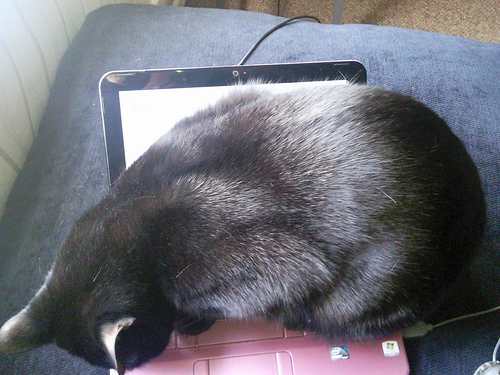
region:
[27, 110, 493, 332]
The cat is standing.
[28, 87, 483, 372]
The cat is sniffing.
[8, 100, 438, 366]
The cat is black.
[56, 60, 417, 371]
The computer is under the cat.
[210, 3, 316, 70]
The cord is black.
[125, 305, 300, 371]
The board is pink.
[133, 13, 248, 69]
The blanket is blue.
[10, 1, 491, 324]
The sun is shining through.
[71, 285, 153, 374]
His ear is shining.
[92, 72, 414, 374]
Small pretty pink lap top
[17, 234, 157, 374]
Curious cat looking at lap top.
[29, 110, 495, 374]
Black cat.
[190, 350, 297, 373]
Pink touch screen mouse.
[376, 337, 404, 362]
Logo of computer manufacturer.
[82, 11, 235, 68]
Comfy blue couch cushion.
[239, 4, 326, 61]
Power supply of computer.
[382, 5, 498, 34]
Short brown shag carpet.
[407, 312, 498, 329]
White computer cord.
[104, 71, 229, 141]
Portion of lap top screen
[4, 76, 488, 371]
cat laying on laptop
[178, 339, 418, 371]
pink windows laptop computer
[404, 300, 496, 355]
green cord connecting to peripheral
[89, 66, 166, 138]
laptop open display monitor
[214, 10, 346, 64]
power cord for laptop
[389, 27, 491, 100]
large blue pillow on couch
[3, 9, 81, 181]
white and green pillow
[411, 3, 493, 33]
different colored brown carpet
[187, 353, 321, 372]
touch pad and two buttons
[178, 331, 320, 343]
keyboard on pink laptop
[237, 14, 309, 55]
a cord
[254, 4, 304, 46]
a cord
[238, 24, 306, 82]
a cord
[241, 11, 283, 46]
a cord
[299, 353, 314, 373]
the laptop is pink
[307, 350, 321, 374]
the laptop is pink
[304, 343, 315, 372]
the laptop is pink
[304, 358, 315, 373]
the laptop is pink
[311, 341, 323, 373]
the laptop is pink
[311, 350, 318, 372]
the laptop is pink